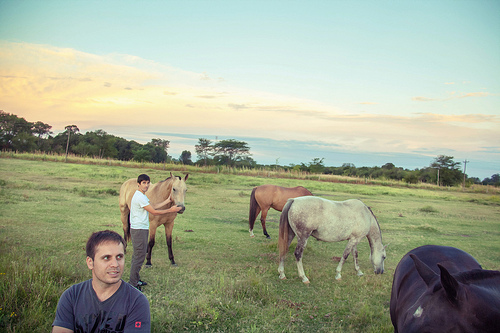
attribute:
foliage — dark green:
[66, 129, 131, 164]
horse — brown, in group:
[383, 244, 498, 331]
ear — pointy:
[406, 251, 440, 291]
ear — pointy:
[429, 259, 466, 306]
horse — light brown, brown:
[116, 169, 196, 270]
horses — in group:
[115, 158, 493, 331]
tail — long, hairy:
[274, 197, 298, 259]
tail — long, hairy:
[245, 186, 260, 230]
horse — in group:
[241, 183, 312, 237]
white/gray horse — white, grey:
[278, 195, 388, 281]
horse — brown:
[249, 185, 311, 230]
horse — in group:
[118, 170, 188, 264]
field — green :
[28, 161, 100, 277]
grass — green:
[37, 134, 474, 210]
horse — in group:
[270, 192, 390, 284]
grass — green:
[0, 148, 499, 328]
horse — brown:
[247, 183, 314, 238]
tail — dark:
[231, 184, 263, 224]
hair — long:
[240, 186, 261, 237]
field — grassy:
[1, 145, 486, 325]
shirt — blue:
[52, 276, 150, 331]